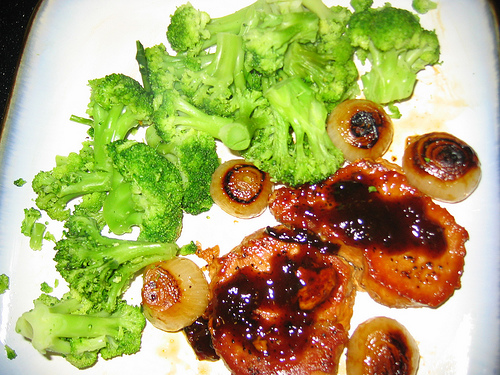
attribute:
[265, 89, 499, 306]
onion — blackened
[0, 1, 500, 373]
plate — white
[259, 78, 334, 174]
vegetable — fresh, green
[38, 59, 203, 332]
vegitable — fresh, green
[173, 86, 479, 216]
onions — carmelized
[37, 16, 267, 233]
broccoli — green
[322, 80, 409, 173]
onion — fried, water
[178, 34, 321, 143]
broccoli — large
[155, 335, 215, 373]
sauce — smeared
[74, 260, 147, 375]
vegetable — green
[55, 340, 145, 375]
plate — white